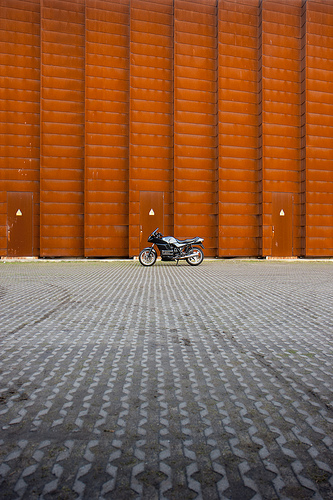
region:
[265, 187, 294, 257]
a rusty door with a white symbol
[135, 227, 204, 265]
a motor bike in front of the rusty wall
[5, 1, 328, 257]
a rusty wall of metal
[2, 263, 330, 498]
the grey ground is patterned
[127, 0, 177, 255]
a rusty section of the wall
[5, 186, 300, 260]
three rusty doors in the wall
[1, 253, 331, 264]
the concrete pad under the wall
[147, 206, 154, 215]
white symbol on a rusty door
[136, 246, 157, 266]
front wheel on the motor bike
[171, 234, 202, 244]
the seat on the motor bike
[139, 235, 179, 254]
this is a cycle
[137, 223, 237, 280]
the cycle is silver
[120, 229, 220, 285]
this is a wheel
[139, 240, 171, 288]
the wheel is silver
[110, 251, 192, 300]
this is a tire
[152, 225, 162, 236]
this is a handle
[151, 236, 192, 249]
this is a seat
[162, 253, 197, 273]
this is a peddle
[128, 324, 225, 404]
this is a carpet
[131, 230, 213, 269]
black motorcycle parked on ground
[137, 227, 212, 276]
black motorcycle in front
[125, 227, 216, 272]
black motorcycle in front of wall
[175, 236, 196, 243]
black seat of motorcycle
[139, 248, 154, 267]
black front wheels of cycle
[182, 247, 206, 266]
back black wheel of cycle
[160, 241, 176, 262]
black body of cycle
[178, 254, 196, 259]
silver exhaust of cycle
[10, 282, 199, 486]
silver metal ground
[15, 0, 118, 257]
tall orange walls of building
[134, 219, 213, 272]
motorcycle on sidewalk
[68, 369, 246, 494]
v pattern on sidewalk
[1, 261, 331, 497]
concrete and metal sidewalk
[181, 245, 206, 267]
wheel on back of motorcycle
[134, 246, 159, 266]
front wheel on motorcycle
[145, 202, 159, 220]
white arrow on door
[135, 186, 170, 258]
brown door on side of wall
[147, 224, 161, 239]
short windshield on front of motorcycle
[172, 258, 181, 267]
kickstand on motorcycle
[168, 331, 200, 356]
dark stain on sidewalk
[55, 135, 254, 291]
bike all by its self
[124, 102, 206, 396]
bike all by its self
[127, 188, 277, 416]
bike all by its self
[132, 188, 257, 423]
bike all by its self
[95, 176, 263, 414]
bike all by its self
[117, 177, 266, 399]
bike all by its self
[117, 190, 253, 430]
bike all by its self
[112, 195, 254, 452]
bike all by its self